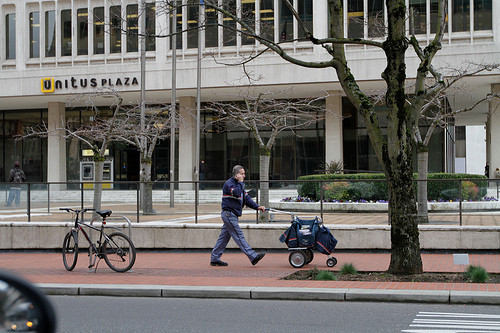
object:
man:
[209, 164, 267, 265]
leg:
[221, 217, 255, 252]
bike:
[58, 207, 136, 273]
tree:
[339, 56, 500, 224]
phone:
[235, 173, 240, 177]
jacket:
[220, 177, 259, 217]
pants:
[209, 210, 258, 262]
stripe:
[225, 211, 253, 257]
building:
[0, 0, 499, 190]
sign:
[39, 76, 139, 92]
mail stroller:
[278, 213, 338, 268]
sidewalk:
[0, 248, 499, 296]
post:
[27, 183, 32, 221]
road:
[32, 291, 499, 332]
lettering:
[400, 310, 499, 332]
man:
[4, 160, 26, 206]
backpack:
[13, 168, 25, 183]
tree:
[13, 86, 166, 222]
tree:
[60, 97, 195, 215]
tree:
[183, 77, 352, 224]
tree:
[72, 0, 499, 275]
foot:
[250, 252, 267, 266]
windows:
[4, 12, 17, 61]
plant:
[463, 263, 490, 283]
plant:
[340, 261, 358, 273]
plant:
[307, 264, 337, 281]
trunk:
[380, 0, 423, 275]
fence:
[0, 178, 499, 225]